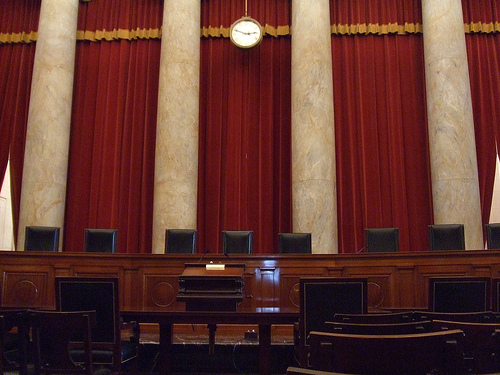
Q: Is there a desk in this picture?
A: Yes, there is a desk.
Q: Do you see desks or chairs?
A: Yes, there is a desk.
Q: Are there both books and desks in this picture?
A: No, there is a desk but no books.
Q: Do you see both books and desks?
A: No, there is a desk but no books.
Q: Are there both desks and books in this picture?
A: No, there is a desk but no books.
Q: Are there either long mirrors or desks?
A: Yes, there is a long desk.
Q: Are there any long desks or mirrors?
A: Yes, there is a long desk.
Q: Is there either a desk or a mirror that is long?
A: Yes, the desk is long.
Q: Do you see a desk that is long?
A: Yes, there is a long desk.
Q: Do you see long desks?
A: Yes, there is a long desk.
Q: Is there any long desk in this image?
A: Yes, there is a long desk.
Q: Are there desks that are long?
A: Yes, there is a desk that is long.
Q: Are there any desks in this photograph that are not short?
A: Yes, there is a long desk.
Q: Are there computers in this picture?
A: No, there are no computers.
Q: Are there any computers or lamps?
A: No, there are no computers or lamps.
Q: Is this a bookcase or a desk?
A: This is a desk.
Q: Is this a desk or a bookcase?
A: This is a desk.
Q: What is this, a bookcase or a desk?
A: This is a desk.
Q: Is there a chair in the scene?
A: Yes, there is a chair.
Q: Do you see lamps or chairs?
A: Yes, there is a chair.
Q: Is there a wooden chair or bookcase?
A: Yes, there is a wood chair.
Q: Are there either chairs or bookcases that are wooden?
A: Yes, the chair is wooden.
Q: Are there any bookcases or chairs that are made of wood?
A: Yes, the chair is made of wood.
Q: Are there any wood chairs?
A: Yes, there is a wood chair.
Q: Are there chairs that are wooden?
A: Yes, there is a chair that is wooden.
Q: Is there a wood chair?
A: Yes, there is a chair that is made of wood.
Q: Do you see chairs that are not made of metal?
A: Yes, there is a chair that is made of wood.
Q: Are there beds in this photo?
A: No, there are no beds.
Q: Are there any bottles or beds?
A: No, there are no beds or bottles.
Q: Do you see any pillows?
A: No, there are no pillows.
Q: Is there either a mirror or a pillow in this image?
A: No, there are no pillows or mirrors.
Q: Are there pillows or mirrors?
A: No, there are no pillows or mirrors.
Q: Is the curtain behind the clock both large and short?
A: No, the curtain is large but long.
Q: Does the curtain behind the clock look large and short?
A: No, the curtain is large but long.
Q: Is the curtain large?
A: Yes, the curtain is large.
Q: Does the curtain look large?
A: Yes, the curtain is large.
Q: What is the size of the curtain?
A: The curtain is large.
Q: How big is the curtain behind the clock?
A: The curtain is large.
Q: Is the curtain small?
A: No, the curtain is large.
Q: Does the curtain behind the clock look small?
A: No, the curtain is large.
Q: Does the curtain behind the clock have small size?
A: No, the curtain is large.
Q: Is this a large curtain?
A: Yes, this is a large curtain.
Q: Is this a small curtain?
A: No, this is a large curtain.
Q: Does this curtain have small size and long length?
A: No, the curtain is long but large.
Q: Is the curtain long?
A: Yes, the curtain is long.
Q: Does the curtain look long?
A: Yes, the curtain is long.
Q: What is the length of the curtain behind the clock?
A: The curtain is long.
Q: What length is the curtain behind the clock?
A: The curtain is long.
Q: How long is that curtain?
A: The curtain is long.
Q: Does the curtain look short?
A: No, the curtain is long.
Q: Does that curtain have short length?
A: No, the curtain is long.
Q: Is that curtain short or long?
A: The curtain is long.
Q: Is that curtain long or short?
A: The curtain is long.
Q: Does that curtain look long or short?
A: The curtain is long.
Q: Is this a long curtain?
A: Yes, this is a long curtain.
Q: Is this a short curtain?
A: No, this is a long curtain.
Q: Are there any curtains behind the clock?
A: Yes, there is a curtain behind the clock.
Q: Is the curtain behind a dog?
A: No, the curtain is behind the clock.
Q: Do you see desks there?
A: Yes, there is a desk.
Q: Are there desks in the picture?
A: Yes, there is a desk.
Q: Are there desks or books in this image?
A: Yes, there is a desk.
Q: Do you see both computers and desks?
A: No, there is a desk but no computers.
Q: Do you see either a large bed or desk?
A: Yes, there is a large desk.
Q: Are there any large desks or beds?
A: Yes, there is a large desk.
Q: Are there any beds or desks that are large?
A: Yes, the desk is large.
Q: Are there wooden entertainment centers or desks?
A: Yes, there is a wood desk.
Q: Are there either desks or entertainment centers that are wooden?
A: Yes, the desk is wooden.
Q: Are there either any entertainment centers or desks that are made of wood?
A: Yes, the desk is made of wood.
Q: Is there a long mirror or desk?
A: Yes, there is a long desk.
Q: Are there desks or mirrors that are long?
A: Yes, the desk is long.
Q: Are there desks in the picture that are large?
A: Yes, there is a large desk.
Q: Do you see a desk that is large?
A: Yes, there is a desk that is large.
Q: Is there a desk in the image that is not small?
A: Yes, there is a large desk.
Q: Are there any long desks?
A: Yes, there is a long desk.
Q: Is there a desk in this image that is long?
A: Yes, there is a desk that is long.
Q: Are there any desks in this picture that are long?
A: Yes, there is a desk that is long.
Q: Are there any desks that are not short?
A: Yes, there is a long desk.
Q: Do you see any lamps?
A: No, there are no lamps.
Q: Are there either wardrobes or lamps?
A: No, there are no lamps or wardrobes.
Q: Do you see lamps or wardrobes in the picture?
A: No, there are no lamps or wardrobes.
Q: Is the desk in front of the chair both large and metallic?
A: No, the desk is large but wooden.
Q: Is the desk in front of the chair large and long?
A: Yes, the desk is large and long.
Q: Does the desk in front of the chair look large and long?
A: Yes, the desk is large and long.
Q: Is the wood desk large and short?
A: No, the desk is large but long.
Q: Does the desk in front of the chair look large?
A: Yes, the desk is large.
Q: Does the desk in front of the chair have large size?
A: Yes, the desk is large.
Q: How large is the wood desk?
A: The desk is large.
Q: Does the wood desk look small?
A: No, the desk is large.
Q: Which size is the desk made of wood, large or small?
A: The desk is large.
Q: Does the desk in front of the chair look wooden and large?
A: Yes, the desk is wooden and large.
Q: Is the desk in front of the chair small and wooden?
A: No, the desk is wooden but large.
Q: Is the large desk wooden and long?
A: Yes, the desk is wooden and long.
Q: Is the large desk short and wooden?
A: No, the desk is wooden but long.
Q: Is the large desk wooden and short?
A: No, the desk is wooden but long.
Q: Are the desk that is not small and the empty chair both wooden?
A: Yes, both the desk and the chair are wooden.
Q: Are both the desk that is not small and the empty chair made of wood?
A: Yes, both the desk and the chair are made of wood.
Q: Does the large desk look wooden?
A: Yes, the desk is wooden.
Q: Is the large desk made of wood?
A: Yes, the desk is made of wood.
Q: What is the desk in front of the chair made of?
A: The desk is made of wood.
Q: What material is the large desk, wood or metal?
A: The desk is made of wood.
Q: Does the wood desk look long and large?
A: Yes, the desk is long and large.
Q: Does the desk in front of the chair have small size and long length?
A: No, the desk is long but large.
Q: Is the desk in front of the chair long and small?
A: No, the desk is long but large.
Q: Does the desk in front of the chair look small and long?
A: No, the desk is long but large.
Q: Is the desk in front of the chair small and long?
A: No, the desk is long but large.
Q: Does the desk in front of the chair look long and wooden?
A: Yes, the desk is long and wooden.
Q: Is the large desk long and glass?
A: No, the desk is long but wooden.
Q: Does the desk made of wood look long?
A: Yes, the desk is long.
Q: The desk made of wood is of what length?
A: The desk is long.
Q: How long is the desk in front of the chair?
A: The desk is long.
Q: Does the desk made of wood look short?
A: No, the desk is long.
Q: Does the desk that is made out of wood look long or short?
A: The desk is long.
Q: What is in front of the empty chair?
A: The desk is in front of the chair.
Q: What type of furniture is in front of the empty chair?
A: The piece of furniture is a desk.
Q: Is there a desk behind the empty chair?
A: No, the desk is in front of the chair.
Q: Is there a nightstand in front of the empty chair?
A: No, there is a desk in front of the chair.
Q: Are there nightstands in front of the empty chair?
A: No, there is a desk in front of the chair.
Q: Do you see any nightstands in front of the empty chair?
A: No, there is a desk in front of the chair.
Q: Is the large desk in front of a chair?
A: Yes, the desk is in front of a chair.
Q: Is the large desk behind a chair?
A: No, the desk is in front of a chair.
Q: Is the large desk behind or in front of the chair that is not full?
A: The desk is in front of the chair.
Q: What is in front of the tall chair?
A: The desk is in front of the chair.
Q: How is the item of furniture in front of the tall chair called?
A: The piece of furniture is a desk.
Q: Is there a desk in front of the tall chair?
A: Yes, there is a desk in front of the chair.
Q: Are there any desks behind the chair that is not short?
A: No, the desk is in front of the chair.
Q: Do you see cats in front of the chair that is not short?
A: No, there is a desk in front of the chair.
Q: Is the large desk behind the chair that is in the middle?
A: No, the desk is in front of the chair.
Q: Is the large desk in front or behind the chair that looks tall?
A: The desk is in front of the chair.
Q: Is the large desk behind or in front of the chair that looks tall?
A: The desk is in front of the chair.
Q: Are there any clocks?
A: Yes, there is a clock.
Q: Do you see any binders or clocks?
A: Yes, there is a clock.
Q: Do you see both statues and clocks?
A: No, there is a clock but no statues.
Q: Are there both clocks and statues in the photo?
A: No, there is a clock but no statues.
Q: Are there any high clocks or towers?
A: Yes, there is a high clock.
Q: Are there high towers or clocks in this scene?
A: Yes, there is a high clock.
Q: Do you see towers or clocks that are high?
A: Yes, the clock is high.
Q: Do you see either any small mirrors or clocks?
A: Yes, there is a small clock.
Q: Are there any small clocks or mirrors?
A: Yes, there is a small clock.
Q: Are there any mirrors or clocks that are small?
A: Yes, the clock is small.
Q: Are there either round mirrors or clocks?
A: Yes, there is a round clock.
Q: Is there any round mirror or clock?
A: Yes, there is a round clock.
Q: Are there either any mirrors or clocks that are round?
A: Yes, the clock is round.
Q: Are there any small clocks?
A: Yes, there is a small clock.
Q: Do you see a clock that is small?
A: Yes, there is a small clock.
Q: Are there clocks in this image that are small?
A: Yes, there is a small clock.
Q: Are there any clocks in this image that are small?
A: Yes, there is a clock that is small.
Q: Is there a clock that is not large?
A: Yes, there is a small clock.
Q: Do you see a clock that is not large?
A: Yes, there is a small clock.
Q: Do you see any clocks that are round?
A: Yes, there is a round clock.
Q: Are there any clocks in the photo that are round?
A: Yes, there is a clock that is round.